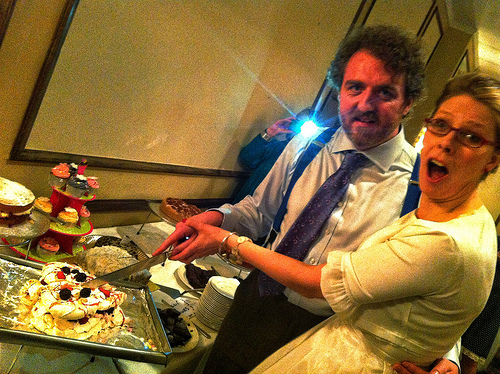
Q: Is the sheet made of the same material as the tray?
A: Yes, both the sheet and the tray are made of metal.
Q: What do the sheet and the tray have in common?
A: The material, both the sheet and the tray are metallic.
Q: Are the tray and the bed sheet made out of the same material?
A: Yes, both the tray and the bed sheet are made of metal.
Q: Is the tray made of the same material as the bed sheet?
A: Yes, both the tray and the bed sheet are made of metal.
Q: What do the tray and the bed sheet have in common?
A: The material, both the tray and the bed sheet are metallic.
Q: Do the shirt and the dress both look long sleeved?
A: Yes, both the shirt and the dress are long sleeved.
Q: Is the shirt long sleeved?
A: Yes, the shirt is long sleeved.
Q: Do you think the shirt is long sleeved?
A: Yes, the shirt is long sleeved.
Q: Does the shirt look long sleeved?
A: Yes, the shirt is long sleeved.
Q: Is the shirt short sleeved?
A: No, the shirt is long sleeved.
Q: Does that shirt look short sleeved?
A: No, the shirt is long sleeved.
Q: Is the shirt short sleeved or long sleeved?
A: The shirt is long sleeved.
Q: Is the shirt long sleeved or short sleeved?
A: The shirt is long sleeved.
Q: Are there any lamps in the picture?
A: No, there are no lamps.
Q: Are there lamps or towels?
A: No, there are no lamps or towels.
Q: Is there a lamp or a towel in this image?
A: No, there are no lamps or towels.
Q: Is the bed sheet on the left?
A: Yes, the bed sheet is on the left of the image.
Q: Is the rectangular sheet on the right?
A: No, the bed sheet is on the left of the image.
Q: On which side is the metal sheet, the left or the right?
A: The bed sheet is on the left of the image.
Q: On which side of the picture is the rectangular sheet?
A: The bed sheet is on the left of the image.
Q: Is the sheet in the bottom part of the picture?
A: Yes, the sheet is in the bottom of the image.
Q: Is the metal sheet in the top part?
A: No, the bed sheet is in the bottom of the image.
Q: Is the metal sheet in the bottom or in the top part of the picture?
A: The sheet is in the bottom of the image.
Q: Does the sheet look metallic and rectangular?
A: Yes, the sheet is metallic and rectangular.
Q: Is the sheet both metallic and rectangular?
A: Yes, the sheet is metallic and rectangular.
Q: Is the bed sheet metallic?
A: Yes, the bed sheet is metallic.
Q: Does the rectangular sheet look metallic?
A: Yes, the bed sheet is metallic.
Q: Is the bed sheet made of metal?
A: Yes, the bed sheet is made of metal.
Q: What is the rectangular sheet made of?
A: The bed sheet is made of metal.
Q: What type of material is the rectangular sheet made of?
A: The bed sheet is made of metal.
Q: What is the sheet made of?
A: The bed sheet is made of metal.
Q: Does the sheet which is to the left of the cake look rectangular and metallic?
A: Yes, the sheet is rectangular and metallic.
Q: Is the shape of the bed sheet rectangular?
A: Yes, the bed sheet is rectangular.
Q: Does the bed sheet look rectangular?
A: Yes, the bed sheet is rectangular.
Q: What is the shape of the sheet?
A: The sheet is rectangular.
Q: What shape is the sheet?
A: The sheet is rectangular.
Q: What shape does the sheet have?
A: The sheet has rectangular shape.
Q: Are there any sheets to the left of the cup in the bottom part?
A: Yes, there is a sheet to the left of the cup.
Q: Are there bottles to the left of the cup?
A: No, there is a sheet to the left of the cup.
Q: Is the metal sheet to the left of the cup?
A: Yes, the bed sheet is to the left of the cup.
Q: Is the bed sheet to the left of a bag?
A: No, the bed sheet is to the left of the cup.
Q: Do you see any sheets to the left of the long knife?
A: Yes, there is a sheet to the left of the knife.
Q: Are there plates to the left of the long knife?
A: No, there is a sheet to the left of the knife.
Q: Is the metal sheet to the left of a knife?
A: Yes, the sheet is to the left of a knife.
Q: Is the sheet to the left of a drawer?
A: No, the sheet is to the left of a knife.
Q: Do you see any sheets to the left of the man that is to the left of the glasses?
A: Yes, there is a sheet to the left of the man.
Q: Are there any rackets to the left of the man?
A: No, there is a sheet to the left of the man.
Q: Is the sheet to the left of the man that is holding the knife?
A: Yes, the sheet is to the left of the man.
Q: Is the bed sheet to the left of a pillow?
A: No, the bed sheet is to the left of the man.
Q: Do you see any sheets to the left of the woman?
A: Yes, there is a sheet to the left of the woman.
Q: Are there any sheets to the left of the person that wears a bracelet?
A: Yes, there is a sheet to the left of the woman.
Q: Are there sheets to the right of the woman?
A: No, the sheet is to the left of the woman.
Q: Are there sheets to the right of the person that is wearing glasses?
A: No, the sheet is to the left of the woman.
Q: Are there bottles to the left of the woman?
A: No, there is a sheet to the left of the woman.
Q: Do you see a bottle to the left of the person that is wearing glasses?
A: No, there is a sheet to the left of the woman.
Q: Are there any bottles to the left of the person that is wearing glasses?
A: No, there is a sheet to the left of the woman.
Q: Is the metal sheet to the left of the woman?
A: Yes, the bed sheet is to the left of the woman.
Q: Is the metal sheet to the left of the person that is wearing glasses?
A: Yes, the bed sheet is to the left of the woman.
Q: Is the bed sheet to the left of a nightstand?
A: No, the bed sheet is to the left of the woman.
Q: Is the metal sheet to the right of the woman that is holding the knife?
A: No, the bed sheet is to the left of the woman.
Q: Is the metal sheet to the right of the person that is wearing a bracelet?
A: No, the bed sheet is to the left of the woman.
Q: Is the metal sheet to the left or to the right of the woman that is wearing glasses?
A: The bed sheet is to the left of the woman.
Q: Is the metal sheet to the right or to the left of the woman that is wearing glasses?
A: The bed sheet is to the left of the woman.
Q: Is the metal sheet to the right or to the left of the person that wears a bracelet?
A: The bed sheet is to the left of the woman.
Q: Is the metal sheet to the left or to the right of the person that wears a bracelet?
A: The bed sheet is to the left of the woman.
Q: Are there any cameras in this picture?
A: Yes, there is a camera.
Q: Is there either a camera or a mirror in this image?
A: Yes, there is a camera.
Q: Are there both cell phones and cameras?
A: No, there is a camera but no cell phones.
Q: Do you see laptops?
A: No, there are no laptops.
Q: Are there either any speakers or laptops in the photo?
A: No, there are no laptops or speakers.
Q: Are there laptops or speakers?
A: No, there are no laptops or speakers.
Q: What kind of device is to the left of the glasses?
A: The device is a camera.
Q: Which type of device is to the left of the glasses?
A: The device is a camera.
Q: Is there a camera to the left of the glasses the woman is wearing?
A: Yes, there is a camera to the left of the glasses.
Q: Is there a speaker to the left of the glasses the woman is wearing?
A: No, there is a camera to the left of the glasses.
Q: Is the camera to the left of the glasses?
A: Yes, the camera is to the left of the glasses.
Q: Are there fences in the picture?
A: No, there are no fences.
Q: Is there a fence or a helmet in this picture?
A: No, there are no fences or helmets.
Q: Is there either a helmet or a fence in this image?
A: No, there are no fences or helmets.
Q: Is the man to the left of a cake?
A: No, the man is to the right of a cake.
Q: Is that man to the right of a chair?
A: No, the man is to the right of a cupcake.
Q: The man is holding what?
A: The man is holding the knife.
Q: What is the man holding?
A: The man is holding the knife.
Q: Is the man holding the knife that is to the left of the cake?
A: Yes, the man is holding the knife.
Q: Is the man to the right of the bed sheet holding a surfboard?
A: No, the man is holding the knife.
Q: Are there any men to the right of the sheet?
A: Yes, there is a man to the right of the sheet.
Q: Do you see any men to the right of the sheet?
A: Yes, there is a man to the right of the sheet.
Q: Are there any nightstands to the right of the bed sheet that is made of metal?
A: No, there is a man to the right of the bed sheet.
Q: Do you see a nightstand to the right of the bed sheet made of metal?
A: No, there is a man to the right of the bed sheet.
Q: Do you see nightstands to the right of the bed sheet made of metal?
A: No, there is a man to the right of the bed sheet.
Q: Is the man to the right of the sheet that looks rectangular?
A: Yes, the man is to the right of the bed sheet.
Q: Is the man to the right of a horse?
A: No, the man is to the right of the bed sheet.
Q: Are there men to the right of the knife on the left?
A: Yes, there is a man to the right of the knife.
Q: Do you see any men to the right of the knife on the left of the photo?
A: Yes, there is a man to the right of the knife.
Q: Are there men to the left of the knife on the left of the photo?
A: No, the man is to the right of the knife.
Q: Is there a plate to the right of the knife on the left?
A: No, there is a man to the right of the knife.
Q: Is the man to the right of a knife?
A: Yes, the man is to the right of a knife.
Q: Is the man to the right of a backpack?
A: No, the man is to the right of a knife.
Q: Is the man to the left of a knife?
A: No, the man is to the right of a knife.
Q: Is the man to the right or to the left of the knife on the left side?
A: The man is to the right of the knife.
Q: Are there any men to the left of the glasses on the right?
A: Yes, there is a man to the left of the glasses.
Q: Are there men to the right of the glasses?
A: No, the man is to the left of the glasses.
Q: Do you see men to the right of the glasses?
A: No, the man is to the left of the glasses.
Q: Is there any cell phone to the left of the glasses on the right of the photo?
A: No, there is a man to the left of the glasses.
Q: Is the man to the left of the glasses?
A: Yes, the man is to the left of the glasses.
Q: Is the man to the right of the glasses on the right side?
A: No, the man is to the left of the glasses.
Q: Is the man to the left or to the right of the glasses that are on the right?
A: The man is to the left of the glasses.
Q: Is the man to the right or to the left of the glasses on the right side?
A: The man is to the left of the glasses.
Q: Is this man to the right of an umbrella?
A: No, the man is to the right of a cake.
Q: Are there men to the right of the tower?
A: Yes, there is a man to the right of the tower.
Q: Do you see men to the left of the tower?
A: No, the man is to the right of the tower.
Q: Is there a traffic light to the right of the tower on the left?
A: No, there is a man to the right of the tower.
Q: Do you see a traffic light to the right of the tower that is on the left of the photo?
A: No, there is a man to the right of the tower.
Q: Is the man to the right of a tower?
A: Yes, the man is to the right of a tower.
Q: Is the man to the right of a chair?
A: No, the man is to the right of a tower.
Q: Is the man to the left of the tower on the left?
A: No, the man is to the right of the tower.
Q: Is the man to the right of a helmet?
A: No, the man is to the right of a cupcake.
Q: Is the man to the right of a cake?
A: Yes, the man is to the right of a cake.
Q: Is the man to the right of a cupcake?
A: Yes, the man is to the right of a cupcake.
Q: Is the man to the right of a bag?
A: No, the man is to the right of a cupcake.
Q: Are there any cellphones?
A: No, there are no cellphones.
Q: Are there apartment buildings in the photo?
A: No, there are no apartment buildings.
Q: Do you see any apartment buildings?
A: No, there are no apartment buildings.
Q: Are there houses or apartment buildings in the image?
A: No, there are no apartment buildings or houses.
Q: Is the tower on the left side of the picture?
A: Yes, the tower is on the left of the image.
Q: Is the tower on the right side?
A: No, the tower is on the left of the image.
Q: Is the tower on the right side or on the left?
A: The tower is on the left of the image.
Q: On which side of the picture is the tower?
A: The tower is on the left of the image.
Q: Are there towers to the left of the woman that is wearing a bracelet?
A: Yes, there is a tower to the left of the woman.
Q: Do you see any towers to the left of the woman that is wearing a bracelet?
A: Yes, there is a tower to the left of the woman.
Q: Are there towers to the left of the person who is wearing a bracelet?
A: Yes, there is a tower to the left of the woman.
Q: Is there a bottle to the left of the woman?
A: No, there is a tower to the left of the woman.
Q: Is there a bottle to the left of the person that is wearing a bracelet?
A: No, there is a tower to the left of the woman.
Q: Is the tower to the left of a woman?
A: Yes, the tower is to the left of a woman.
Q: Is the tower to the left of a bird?
A: No, the tower is to the left of a woman.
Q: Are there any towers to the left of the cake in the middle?
A: Yes, there is a tower to the left of the cake.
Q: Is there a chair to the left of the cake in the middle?
A: No, there is a tower to the left of the cake.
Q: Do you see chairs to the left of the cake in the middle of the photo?
A: No, there is a tower to the left of the cake.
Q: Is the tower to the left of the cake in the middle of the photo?
A: Yes, the tower is to the left of the cake.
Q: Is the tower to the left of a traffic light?
A: No, the tower is to the left of the cake.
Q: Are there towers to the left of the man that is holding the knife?
A: Yes, there is a tower to the left of the man.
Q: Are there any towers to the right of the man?
A: No, the tower is to the left of the man.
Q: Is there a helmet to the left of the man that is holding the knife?
A: No, there is a tower to the left of the man.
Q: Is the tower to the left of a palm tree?
A: No, the tower is to the left of the man.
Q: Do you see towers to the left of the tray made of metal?
A: Yes, there is a tower to the left of the tray.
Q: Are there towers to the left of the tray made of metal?
A: Yes, there is a tower to the left of the tray.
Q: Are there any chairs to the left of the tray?
A: No, there is a tower to the left of the tray.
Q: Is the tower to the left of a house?
A: No, the tower is to the left of the tray.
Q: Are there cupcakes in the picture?
A: Yes, there is a cupcake.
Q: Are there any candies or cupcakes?
A: Yes, there is a cupcake.